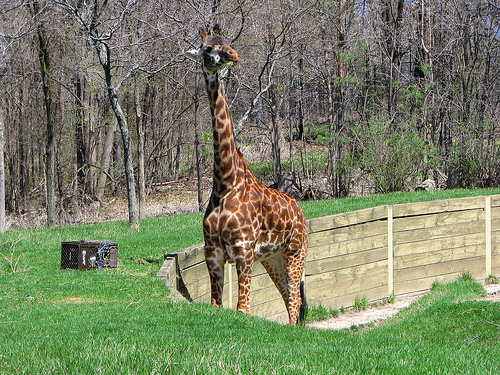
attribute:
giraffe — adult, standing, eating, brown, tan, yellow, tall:
[184, 22, 312, 329]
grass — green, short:
[3, 188, 498, 375]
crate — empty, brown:
[58, 237, 120, 273]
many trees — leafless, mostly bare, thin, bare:
[1, 0, 499, 229]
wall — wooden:
[159, 195, 499, 313]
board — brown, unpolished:
[388, 195, 490, 217]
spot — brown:
[220, 111, 228, 122]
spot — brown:
[210, 97, 226, 116]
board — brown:
[392, 208, 486, 233]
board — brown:
[390, 220, 488, 247]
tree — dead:
[88, 20, 141, 232]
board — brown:
[389, 233, 488, 258]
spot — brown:
[218, 141, 232, 161]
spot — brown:
[212, 128, 220, 144]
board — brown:
[394, 243, 491, 270]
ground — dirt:
[301, 281, 499, 336]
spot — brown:
[241, 225, 256, 243]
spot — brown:
[231, 244, 243, 261]